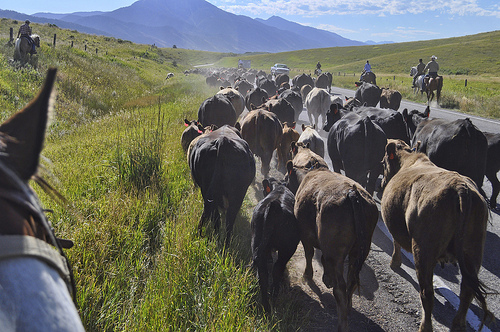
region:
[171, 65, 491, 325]
many horses walking along dusty road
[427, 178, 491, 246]
backside of brown horse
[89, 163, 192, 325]
sunlit patch of long grass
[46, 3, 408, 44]
mountains with blue sky and clouds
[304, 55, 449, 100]
several people on horseback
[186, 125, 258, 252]
dark cow walking in sunlit grass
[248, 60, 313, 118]
one car in front of lots of cows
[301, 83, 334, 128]
one light colored cow walking on road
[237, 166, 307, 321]
this is a calf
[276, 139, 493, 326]
these are the cows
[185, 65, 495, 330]
a herd of cows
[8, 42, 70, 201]
this is an ear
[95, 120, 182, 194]
this is a shrub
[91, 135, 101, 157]
this is a grass blade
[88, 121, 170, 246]
this is the grass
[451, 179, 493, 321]
this is a tail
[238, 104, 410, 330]
this is an animal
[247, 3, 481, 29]
clouds in the sky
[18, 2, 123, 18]
clear blue sky behind the mountain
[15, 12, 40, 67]
a man riding a horse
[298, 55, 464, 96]
people riding horses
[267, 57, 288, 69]
a car parked on the street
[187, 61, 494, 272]
cows walking down the street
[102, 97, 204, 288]
tall grass next to the street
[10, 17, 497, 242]
horses walking next to cows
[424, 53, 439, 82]
a man wearing a white cowboy hat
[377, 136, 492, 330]
A brown cow on the road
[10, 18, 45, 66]
A person riding the hourse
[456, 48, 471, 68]
Part of the green field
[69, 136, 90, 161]
Part of the green grass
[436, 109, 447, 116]
Part of the road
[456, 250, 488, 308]
Part of the cow's tail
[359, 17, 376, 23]
Part of the blue sky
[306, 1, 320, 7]
Part of the cloud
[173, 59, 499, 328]
a herd of cows on a road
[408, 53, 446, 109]
two men on horseback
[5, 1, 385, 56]
large grey mountain in the background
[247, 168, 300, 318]
a small black calf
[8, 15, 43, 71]
a man on a horse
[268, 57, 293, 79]
a white vehicle in front of a herd of cattle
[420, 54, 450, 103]
a man on horseback wears a hat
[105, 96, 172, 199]
tall grass growing next to a road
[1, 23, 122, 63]
wooden fence posts on a hill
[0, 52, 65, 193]
ear of a brown horse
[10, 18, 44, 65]
a person riding a horse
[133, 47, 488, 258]
animals on the street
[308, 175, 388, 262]
back of the cow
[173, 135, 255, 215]
back of the black cow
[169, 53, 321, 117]
cows in the distance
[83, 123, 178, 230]
grass next to the cows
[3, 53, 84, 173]
ear of the animal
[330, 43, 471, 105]
people on the horses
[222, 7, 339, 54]
hills in the distance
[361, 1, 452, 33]
clouds above the land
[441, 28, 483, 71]
green grass on the ground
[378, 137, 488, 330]
brown cow walking along the roadside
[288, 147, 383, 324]
brown cow walking along the roadside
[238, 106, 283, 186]
brown cow walking along the roadside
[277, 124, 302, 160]
brown cow walking along the roadside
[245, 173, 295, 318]
black cow walking along the roadside